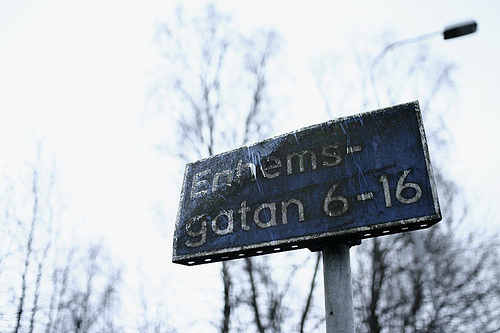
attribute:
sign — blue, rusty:
[163, 128, 446, 255]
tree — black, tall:
[119, 20, 472, 309]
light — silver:
[337, 21, 484, 104]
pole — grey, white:
[303, 243, 368, 317]